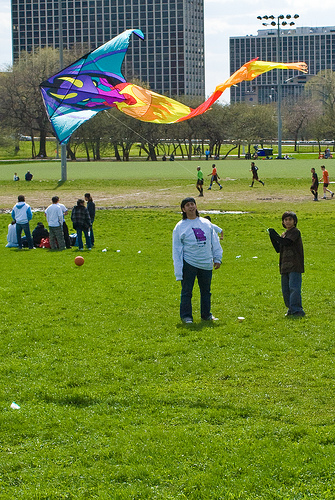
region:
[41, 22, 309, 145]
long multi colored kite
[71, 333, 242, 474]
green grass in park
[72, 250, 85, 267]
basketball rolling on ground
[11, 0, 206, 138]
tall building with many windows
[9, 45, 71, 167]
tree with light green buds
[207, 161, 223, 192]
man in orange tee shirt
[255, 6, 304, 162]
tall light post with many bulbs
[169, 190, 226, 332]
boy in light grey sweatshirt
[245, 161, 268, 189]
man running across field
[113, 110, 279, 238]
extended kite string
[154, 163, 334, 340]
boy flying a kite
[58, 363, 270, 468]
green grass in the field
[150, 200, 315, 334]
two people standing in a park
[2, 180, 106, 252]
group of children sitting down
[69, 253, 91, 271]
basketball sitting in the grass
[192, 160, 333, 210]
people playing soccer in the background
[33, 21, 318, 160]
purple and yellow kite flying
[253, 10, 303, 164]
stadium lights at the park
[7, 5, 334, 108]
large buildings behind the park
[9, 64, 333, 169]
trees with leaves in the background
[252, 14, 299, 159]
a large light pole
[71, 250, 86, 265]
a small ball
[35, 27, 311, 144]
a large colorful kite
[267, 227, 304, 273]
a boy's long sleeve sweater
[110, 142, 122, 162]
the branch of a tree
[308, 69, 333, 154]
a tall green tree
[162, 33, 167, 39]
a window of a building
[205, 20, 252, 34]
part of a white cloud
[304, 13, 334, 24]
part of a blue sky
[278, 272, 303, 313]
a boy's blue jean pants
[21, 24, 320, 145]
kite flying in sky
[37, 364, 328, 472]
field of grass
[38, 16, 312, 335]
boy is flying kite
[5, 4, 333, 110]
tall buildings in the background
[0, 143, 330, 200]
people playing game in park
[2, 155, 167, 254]
group of people watching game at park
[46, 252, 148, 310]
a basketball on the ground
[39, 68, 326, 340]
man watching boy fly kite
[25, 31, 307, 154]
colorful kite flying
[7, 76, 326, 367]
people enjoying the park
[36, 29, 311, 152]
a colorful kite flying in air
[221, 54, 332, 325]
a child flying a kite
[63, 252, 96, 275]
a basketball on the grass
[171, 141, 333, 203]
people playing ball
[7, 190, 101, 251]
people relaxing at the park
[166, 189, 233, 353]
person with dark hair and white shirt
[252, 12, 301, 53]
stadium lights on a pole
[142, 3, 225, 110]
a tall office building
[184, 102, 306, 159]
trees along roadside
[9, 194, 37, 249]
person in blue and white hoodie